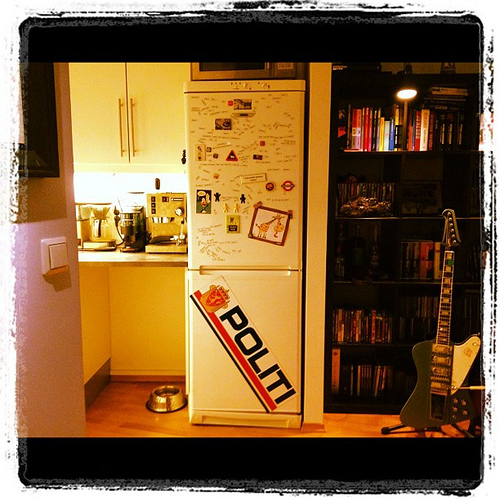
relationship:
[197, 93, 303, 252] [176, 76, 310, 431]
magnets on refrigerator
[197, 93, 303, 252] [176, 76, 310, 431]
magnets on bridge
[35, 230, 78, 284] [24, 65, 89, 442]
thermastat mounted on wall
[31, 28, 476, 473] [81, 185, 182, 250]
kitchen with appliances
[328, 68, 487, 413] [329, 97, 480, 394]
book case with books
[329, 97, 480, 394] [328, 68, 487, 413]
books in a shelf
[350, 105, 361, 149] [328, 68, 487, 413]
book in a shelf